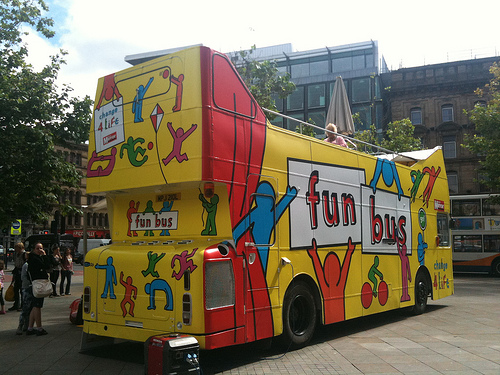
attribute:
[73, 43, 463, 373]
bus — yellow, fun, black, top, red, double decker, brown, white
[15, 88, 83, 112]
leave — green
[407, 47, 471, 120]
wall — brown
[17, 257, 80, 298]
bag — white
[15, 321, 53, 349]
shoe — black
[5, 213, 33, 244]
sign — neon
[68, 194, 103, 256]
light — stop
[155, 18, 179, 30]
sky — blue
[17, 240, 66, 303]
woman — standing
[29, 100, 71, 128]
tree — green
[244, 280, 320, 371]
wheel — black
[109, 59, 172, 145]
human — blue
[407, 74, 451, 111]
building — brown